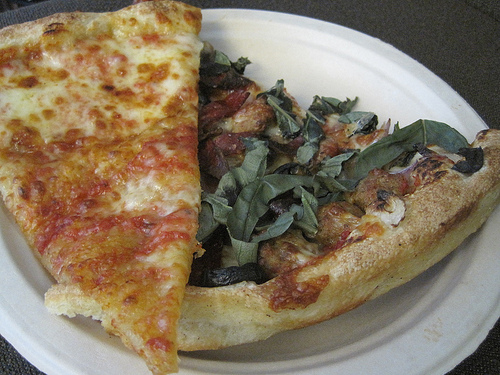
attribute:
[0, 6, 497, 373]
plate — white, ceramic, paper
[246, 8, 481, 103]
white plate — white 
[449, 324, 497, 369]
flat edge — flat 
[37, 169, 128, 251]
sauce — red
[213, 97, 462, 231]
herbs — green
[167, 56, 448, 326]
slice — green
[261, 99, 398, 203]
toppings — red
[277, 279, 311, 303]
spot — dark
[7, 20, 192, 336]
cheese — melted